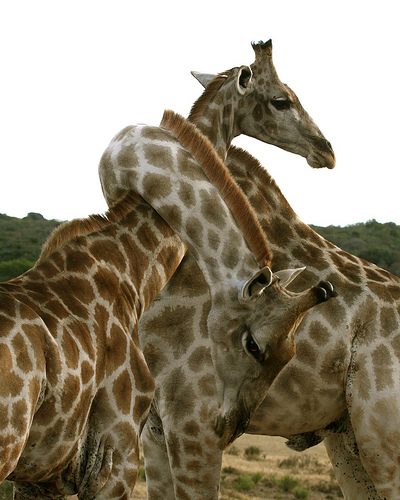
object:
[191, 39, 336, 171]
giraffe head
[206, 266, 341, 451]
giraffe head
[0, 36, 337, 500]
giraffe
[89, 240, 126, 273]
brown spot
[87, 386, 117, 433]
brown spot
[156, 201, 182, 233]
brown spot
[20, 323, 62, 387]
brown spot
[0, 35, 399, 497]
giraffes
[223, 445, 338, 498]
sand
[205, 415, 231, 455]
lip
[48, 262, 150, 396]
pattern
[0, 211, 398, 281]
hill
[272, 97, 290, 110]
eye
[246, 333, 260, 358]
eye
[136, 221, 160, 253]
spot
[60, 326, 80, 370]
spot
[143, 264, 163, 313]
brown spot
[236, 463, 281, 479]
ground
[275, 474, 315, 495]
grass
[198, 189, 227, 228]
spot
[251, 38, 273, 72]
horn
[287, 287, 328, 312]
horn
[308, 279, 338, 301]
horn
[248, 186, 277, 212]
brown spots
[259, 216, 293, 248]
brown spots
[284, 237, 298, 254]
tan lines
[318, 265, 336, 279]
tan lines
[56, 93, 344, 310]
necks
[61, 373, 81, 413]
spot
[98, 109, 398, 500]
giraffe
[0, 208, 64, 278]
trees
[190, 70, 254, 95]
ears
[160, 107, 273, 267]
mane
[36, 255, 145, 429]
side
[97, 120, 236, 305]
neck